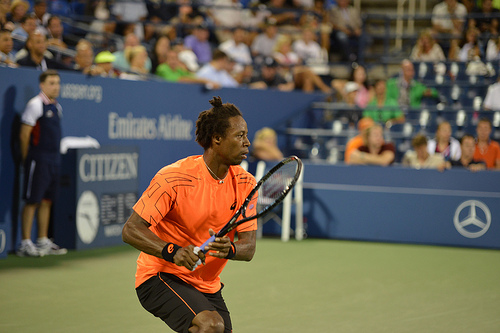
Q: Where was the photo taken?
A: Tennis court.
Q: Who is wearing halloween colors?
A: Tennis player.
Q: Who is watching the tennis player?
A: Audience.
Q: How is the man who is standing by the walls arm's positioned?
A: Behind back.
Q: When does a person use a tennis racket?
A: While playing tennis.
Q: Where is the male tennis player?
A: Tennis court.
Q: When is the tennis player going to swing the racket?
A: When ball comes.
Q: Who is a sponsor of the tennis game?
A: Emirates airline.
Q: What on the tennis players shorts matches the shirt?
A: Orange stripe.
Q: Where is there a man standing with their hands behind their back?
A: Against wall.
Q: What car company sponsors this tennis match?
A: Mercedes Benz.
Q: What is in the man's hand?
A: A tennis racket.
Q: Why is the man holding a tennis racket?
A: To play tennis.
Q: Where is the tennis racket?
A: In the man's hand.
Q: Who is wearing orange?
A: The tennis player.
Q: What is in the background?
A: The audience.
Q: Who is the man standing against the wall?
A: A line judge.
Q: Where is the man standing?
A: On a tennis court.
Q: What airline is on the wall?
A: Emirates.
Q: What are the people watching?
A: A tennis match.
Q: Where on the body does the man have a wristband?
A: Right wrist.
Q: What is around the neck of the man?
A: Necklace.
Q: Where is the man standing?
A: Tennis court.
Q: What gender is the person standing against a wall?
A: Male.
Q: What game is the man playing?
A: Tennis.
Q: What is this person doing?
A: Playing tennis.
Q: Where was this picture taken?
A: At a tennis match.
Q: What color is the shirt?
A: Orange.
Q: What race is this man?
A: Black.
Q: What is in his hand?
A: A tennis racquet.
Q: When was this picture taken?
A: During the afternoon.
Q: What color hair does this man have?
A: Brown.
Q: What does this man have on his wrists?
A: Wristbands.